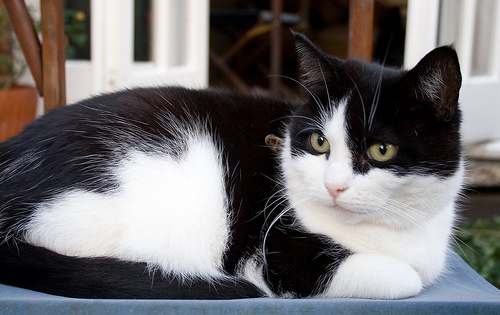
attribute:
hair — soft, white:
[284, 150, 455, 298]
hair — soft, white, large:
[27, 126, 232, 283]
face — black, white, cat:
[276, 26, 470, 231]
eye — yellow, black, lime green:
[365, 139, 403, 162]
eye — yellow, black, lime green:
[295, 128, 332, 158]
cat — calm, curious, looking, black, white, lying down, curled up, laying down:
[5, 29, 467, 298]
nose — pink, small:
[321, 172, 350, 199]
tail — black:
[6, 238, 265, 300]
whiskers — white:
[257, 167, 322, 263]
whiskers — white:
[267, 63, 415, 132]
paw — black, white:
[269, 223, 426, 305]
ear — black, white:
[288, 29, 342, 92]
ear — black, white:
[408, 45, 465, 120]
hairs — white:
[299, 48, 323, 88]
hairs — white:
[422, 72, 444, 106]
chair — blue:
[2, 240, 500, 312]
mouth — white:
[320, 198, 367, 221]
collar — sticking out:
[261, 131, 284, 154]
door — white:
[69, 0, 208, 93]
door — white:
[406, 0, 499, 146]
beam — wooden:
[12, 2, 71, 124]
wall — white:
[1, 0, 211, 102]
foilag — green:
[454, 220, 499, 286]